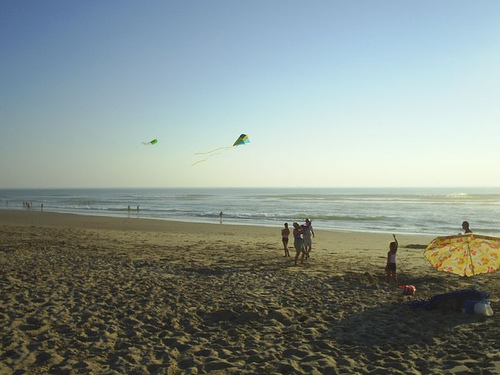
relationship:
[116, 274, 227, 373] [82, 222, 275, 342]
footprints on beach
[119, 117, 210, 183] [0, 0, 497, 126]
cloud in sky